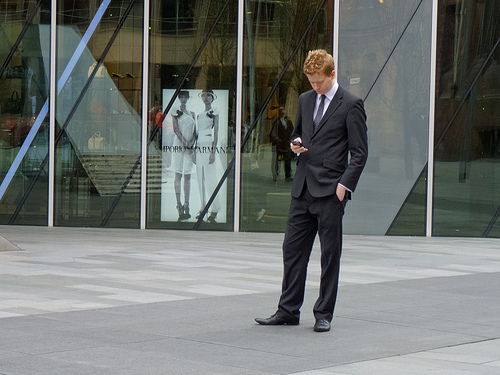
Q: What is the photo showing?
A: It is showing a street.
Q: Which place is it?
A: It is a street.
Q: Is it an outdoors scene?
A: Yes, it is outdoors.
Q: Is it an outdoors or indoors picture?
A: It is outdoors.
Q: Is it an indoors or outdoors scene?
A: It is outdoors.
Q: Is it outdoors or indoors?
A: It is outdoors.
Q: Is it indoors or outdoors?
A: It is outdoors.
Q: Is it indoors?
A: No, it is outdoors.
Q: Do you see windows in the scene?
A: Yes, there is a window.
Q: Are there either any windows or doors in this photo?
A: Yes, there is a window.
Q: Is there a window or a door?
A: Yes, there is a window.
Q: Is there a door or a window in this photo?
A: Yes, there is a window.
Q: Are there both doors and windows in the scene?
A: No, there is a window but no doors.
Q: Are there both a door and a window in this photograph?
A: No, there is a window but no doors.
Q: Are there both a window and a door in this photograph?
A: No, there is a window but no doors.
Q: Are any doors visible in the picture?
A: No, there are no doors.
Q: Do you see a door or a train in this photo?
A: No, there are no doors or trains.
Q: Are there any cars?
A: No, there are no cars.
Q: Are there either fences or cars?
A: No, there are no cars or fences.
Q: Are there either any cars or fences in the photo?
A: No, there are no cars or fences.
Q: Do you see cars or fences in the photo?
A: No, there are no cars or fences.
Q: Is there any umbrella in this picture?
A: No, there are no umbrellas.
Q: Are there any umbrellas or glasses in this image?
A: No, there are no umbrellas or glasses.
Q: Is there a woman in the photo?
A: Yes, there is a woman.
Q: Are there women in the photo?
A: Yes, there is a woman.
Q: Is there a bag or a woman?
A: Yes, there is a woman.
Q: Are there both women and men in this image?
A: Yes, there are both a woman and a man.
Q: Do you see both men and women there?
A: Yes, there are both a woman and a man.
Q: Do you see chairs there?
A: No, there are no chairs.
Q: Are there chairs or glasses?
A: No, there are no chairs or glasses.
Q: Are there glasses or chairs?
A: No, there are no chairs or glasses.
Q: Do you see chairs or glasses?
A: No, there are no chairs or glasses.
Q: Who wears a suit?
A: The woman wears a suit.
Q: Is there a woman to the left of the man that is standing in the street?
A: Yes, there is a woman to the left of the man.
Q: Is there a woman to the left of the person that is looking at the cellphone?
A: Yes, there is a woman to the left of the man.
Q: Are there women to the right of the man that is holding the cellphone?
A: No, the woman is to the left of the man.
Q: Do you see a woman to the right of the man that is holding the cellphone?
A: No, the woman is to the left of the man.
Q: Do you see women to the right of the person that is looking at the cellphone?
A: No, the woman is to the left of the man.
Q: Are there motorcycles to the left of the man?
A: No, there is a woman to the left of the man.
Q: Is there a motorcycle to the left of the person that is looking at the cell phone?
A: No, there is a woman to the left of the man.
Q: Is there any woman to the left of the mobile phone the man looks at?
A: Yes, there is a woman to the left of the mobile phone.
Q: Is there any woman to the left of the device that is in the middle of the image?
A: Yes, there is a woman to the left of the mobile phone.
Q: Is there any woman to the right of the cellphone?
A: No, the woman is to the left of the cellphone.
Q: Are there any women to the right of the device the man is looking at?
A: No, the woman is to the left of the cellphone.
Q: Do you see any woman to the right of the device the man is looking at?
A: No, the woman is to the left of the cellphone.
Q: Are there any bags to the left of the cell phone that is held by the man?
A: No, there is a woman to the left of the mobile phone.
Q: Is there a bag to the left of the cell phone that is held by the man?
A: No, there is a woman to the left of the mobile phone.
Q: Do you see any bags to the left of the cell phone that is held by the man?
A: No, there is a woman to the left of the mobile phone.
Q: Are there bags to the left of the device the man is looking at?
A: No, there is a woman to the left of the mobile phone.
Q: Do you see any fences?
A: No, there are no fences.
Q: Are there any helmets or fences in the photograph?
A: No, there are no fences or helmets.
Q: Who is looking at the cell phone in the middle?
A: The man is looking at the mobile phone.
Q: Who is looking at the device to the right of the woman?
A: The man is looking at the mobile phone.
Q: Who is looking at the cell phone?
A: The man is looking at the mobile phone.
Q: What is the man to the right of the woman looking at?
A: The man is looking at the cell phone.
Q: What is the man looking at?
A: The man is looking at the cell phone.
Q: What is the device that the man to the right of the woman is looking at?
A: The device is a cell phone.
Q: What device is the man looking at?
A: The man is looking at the cellphone.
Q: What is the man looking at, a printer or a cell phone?
A: The man is looking at a cell phone.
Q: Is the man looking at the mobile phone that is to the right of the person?
A: Yes, the man is looking at the cellphone.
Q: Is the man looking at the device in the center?
A: Yes, the man is looking at the cellphone.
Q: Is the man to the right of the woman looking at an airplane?
A: No, the man is looking at the cellphone.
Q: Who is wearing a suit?
A: The man is wearing a suit.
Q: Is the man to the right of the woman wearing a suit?
A: Yes, the man is wearing a suit.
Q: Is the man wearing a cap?
A: No, the man is wearing a suit.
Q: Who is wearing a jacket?
A: The man is wearing a jacket.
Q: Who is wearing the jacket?
A: The man is wearing a jacket.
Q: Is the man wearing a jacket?
A: Yes, the man is wearing a jacket.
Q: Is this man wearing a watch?
A: No, the man is wearing a jacket.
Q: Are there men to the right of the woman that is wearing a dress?
A: Yes, there is a man to the right of the woman.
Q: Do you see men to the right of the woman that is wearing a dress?
A: Yes, there is a man to the right of the woman.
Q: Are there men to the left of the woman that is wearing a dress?
A: No, the man is to the right of the woman.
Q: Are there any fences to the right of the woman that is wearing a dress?
A: No, there is a man to the right of the woman.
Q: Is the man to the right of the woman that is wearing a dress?
A: Yes, the man is to the right of the woman.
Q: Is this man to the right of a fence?
A: No, the man is to the right of the woman.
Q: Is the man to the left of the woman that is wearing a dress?
A: No, the man is to the right of the woman.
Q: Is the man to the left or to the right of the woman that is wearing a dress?
A: The man is to the right of the woman.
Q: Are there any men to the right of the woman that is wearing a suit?
A: Yes, there is a man to the right of the woman.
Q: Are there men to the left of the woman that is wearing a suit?
A: No, the man is to the right of the woman.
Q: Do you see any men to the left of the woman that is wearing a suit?
A: No, the man is to the right of the woman.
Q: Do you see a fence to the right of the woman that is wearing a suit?
A: No, there is a man to the right of the woman.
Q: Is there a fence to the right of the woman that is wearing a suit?
A: No, there is a man to the right of the woman.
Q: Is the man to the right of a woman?
A: Yes, the man is to the right of a woman.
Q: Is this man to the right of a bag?
A: No, the man is to the right of a woman.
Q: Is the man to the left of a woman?
A: No, the man is to the right of a woman.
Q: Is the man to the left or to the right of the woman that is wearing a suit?
A: The man is to the right of the woman.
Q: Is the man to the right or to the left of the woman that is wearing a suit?
A: The man is to the right of the woman.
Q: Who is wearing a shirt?
A: The man is wearing a shirt.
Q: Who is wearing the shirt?
A: The man is wearing a shirt.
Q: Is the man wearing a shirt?
A: Yes, the man is wearing a shirt.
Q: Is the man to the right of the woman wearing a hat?
A: No, the man is wearing a shirt.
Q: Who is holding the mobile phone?
A: The man is holding the mobile phone.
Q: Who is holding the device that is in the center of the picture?
A: The man is holding the mobile phone.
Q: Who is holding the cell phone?
A: The man is holding the mobile phone.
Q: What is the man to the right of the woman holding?
A: The man is holding the cellphone.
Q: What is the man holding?
A: The man is holding the cellphone.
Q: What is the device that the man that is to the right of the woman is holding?
A: The device is a cell phone.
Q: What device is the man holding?
A: The man is holding the cell phone.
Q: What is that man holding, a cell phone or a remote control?
A: The man is holding a cell phone.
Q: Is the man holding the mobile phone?
A: Yes, the man is holding the mobile phone.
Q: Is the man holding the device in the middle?
A: Yes, the man is holding the mobile phone.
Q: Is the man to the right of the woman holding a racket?
A: No, the man is holding the mobile phone.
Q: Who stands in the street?
A: The man stands in the street.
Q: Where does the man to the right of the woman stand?
A: The man stands in the street.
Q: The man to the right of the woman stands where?
A: The man stands in the street.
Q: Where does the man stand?
A: The man stands in the street.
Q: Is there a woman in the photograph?
A: Yes, there is a woman.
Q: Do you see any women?
A: Yes, there is a woman.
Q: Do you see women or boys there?
A: Yes, there is a woman.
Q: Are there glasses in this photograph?
A: No, there are no glasses.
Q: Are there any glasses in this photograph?
A: No, there are no glasses.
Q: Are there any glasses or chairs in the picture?
A: No, there are no glasses or chairs.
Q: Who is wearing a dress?
A: The woman is wearing a dress.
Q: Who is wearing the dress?
A: The woman is wearing a dress.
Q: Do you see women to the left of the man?
A: Yes, there is a woman to the left of the man.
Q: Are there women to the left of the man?
A: Yes, there is a woman to the left of the man.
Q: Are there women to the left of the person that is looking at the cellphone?
A: Yes, there is a woman to the left of the man.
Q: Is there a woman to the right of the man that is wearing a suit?
A: No, the woman is to the left of the man.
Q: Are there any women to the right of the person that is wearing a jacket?
A: No, the woman is to the left of the man.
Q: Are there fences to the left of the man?
A: No, there is a woman to the left of the man.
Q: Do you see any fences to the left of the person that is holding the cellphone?
A: No, there is a woman to the left of the man.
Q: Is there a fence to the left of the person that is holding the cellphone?
A: No, there is a woman to the left of the man.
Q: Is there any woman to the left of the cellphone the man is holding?
A: Yes, there is a woman to the left of the mobile phone.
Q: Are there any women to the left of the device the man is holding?
A: Yes, there is a woman to the left of the mobile phone.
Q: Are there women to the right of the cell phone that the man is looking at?
A: No, the woman is to the left of the mobile phone.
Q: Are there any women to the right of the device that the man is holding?
A: No, the woman is to the left of the mobile phone.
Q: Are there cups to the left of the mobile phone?
A: No, there is a woman to the left of the mobile phone.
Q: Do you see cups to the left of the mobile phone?
A: No, there is a woman to the left of the mobile phone.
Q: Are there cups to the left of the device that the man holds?
A: No, there is a woman to the left of the mobile phone.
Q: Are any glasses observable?
A: No, there are no glasses.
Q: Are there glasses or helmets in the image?
A: No, there are no glasses or helmets.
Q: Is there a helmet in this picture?
A: No, there are no helmets.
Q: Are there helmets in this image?
A: No, there are no helmets.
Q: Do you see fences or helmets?
A: No, there are no helmets or fences.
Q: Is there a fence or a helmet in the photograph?
A: No, there are no helmets or fences.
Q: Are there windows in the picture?
A: Yes, there is a window.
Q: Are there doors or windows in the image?
A: Yes, there is a window.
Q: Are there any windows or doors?
A: Yes, there is a window.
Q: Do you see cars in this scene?
A: No, there are no cars.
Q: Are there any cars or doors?
A: No, there are no cars or doors.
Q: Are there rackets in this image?
A: No, there are no rackets.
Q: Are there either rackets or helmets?
A: No, there are no rackets or helmets.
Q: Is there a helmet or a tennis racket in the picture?
A: No, there are no rackets or helmets.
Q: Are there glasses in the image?
A: No, there are no glasses.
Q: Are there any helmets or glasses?
A: No, there are no glasses or helmets.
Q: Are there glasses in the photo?
A: No, there are no glasses.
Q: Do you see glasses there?
A: No, there are no glasses.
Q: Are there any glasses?
A: No, there are no glasses.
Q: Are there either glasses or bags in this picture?
A: No, there are no glasses or bags.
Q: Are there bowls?
A: No, there are no bowls.